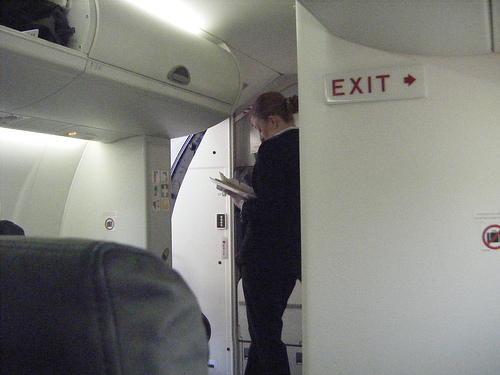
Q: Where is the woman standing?
A: Leaning against a wall.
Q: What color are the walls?
A: White.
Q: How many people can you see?
A: 2.